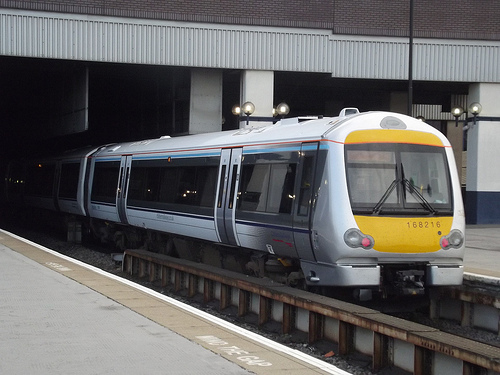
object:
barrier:
[120, 231, 500, 368]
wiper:
[379, 180, 477, 215]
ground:
[328, 205, 333, 216]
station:
[0, 0, 500, 375]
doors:
[215, 148, 244, 249]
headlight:
[343, 228, 375, 251]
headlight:
[439, 229, 465, 251]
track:
[6, 212, 500, 374]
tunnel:
[0, 55, 470, 231]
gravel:
[7, 222, 392, 374]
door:
[294, 139, 320, 264]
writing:
[193, 321, 274, 371]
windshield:
[342, 141, 454, 221]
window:
[127, 157, 220, 220]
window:
[234, 148, 308, 231]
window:
[89, 160, 123, 208]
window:
[52, 158, 83, 200]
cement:
[0, 229, 351, 374]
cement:
[460, 225, 499, 282]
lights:
[231, 103, 241, 115]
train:
[22, 107, 465, 301]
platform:
[0, 228, 353, 375]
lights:
[241, 101, 256, 114]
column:
[240, 68, 275, 129]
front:
[342, 125, 465, 254]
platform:
[465, 224, 499, 285]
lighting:
[451, 104, 464, 116]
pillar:
[466, 82, 499, 225]